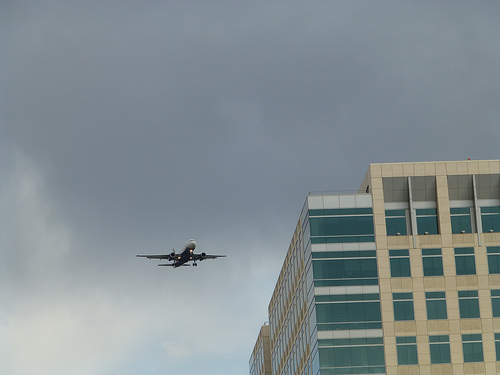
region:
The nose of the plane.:
[185, 238, 203, 247]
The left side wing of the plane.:
[144, 245, 181, 260]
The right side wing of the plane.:
[194, 250, 230, 262]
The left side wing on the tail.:
[159, 257, 176, 267]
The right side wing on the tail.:
[182, 261, 192, 269]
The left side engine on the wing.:
[168, 249, 178, 261]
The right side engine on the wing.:
[197, 248, 214, 267]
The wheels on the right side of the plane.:
[191, 261, 201, 268]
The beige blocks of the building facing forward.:
[362, 164, 497, 368]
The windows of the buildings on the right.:
[215, 211, 497, 373]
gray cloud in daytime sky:
[95, 64, 222, 169]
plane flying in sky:
[133, 230, 233, 281]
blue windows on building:
[307, 201, 377, 251]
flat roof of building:
[371, 147, 485, 175]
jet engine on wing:
[194, 249, 211, 266]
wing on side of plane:
[134, 249, 181, 263]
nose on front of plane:
[180, 233, 203, 255]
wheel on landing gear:
[185, 258, 205, 273]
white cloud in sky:
[19, 313, 101, 365]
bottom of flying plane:
[176, 249, 196, 269]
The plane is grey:
[97, 226, 240, 293]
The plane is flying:
[108, 218, 226, 279]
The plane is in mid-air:
[118, 219, 235, 291]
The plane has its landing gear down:
[140, 213, 228, 284]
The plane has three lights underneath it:
[137, 226, 225, 286]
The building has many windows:
[262, 156, 492, 373]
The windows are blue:
[311, 169, 493, 374]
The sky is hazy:
[55, 60, 275, 182]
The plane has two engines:
[136, 229, 236, 295]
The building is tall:
[256, 153, 488, 374]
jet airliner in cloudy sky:
[126, 214, 238, 293]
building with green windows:
[304, 188, 380, 366]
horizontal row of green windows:
[308, 202, 376, 247]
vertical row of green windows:
[305, 190, 391, 374]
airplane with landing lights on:
[129, 220, 229, 290]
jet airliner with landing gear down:
[113, 199, 233, 299]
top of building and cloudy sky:
[232, 130, 452, 346]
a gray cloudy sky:
[28, 42, 133, 355]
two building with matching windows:
[228, 135, 349, 373]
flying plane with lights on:
[120, 217, 251, 290]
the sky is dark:
[159, 53, 294, 121]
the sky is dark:
[108, 26, 325, 183]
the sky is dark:
[61, 9, 273, 218]